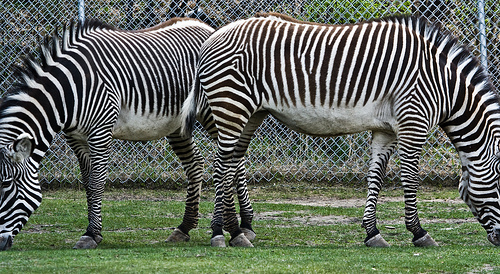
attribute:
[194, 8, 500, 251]
zebra — striped, eating, facing, black, soft, grazing, white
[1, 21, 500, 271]
zebras — blending, grazing, eating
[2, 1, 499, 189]
fence — chain linked, silver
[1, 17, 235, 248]
zebra — facing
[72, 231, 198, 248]
hooves — black, grey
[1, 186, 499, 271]
grass — dusty, flat, green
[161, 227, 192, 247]
hoof — rounded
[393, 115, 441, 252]
leg — black, white, striped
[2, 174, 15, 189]
eye — black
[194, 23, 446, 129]
stripes — black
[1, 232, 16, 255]
mouth — black